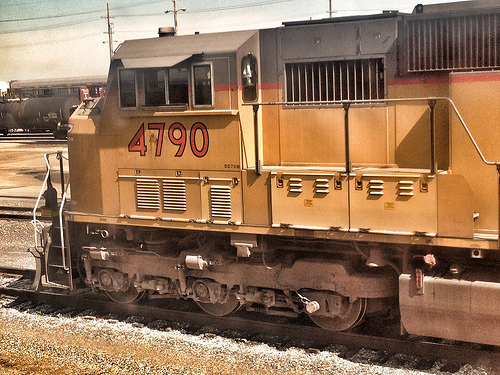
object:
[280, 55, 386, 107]
window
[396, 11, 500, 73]
window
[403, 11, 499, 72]
railing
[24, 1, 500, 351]
train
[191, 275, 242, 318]
wheel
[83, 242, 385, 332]
wheels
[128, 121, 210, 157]
number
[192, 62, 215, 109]
window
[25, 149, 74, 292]
stairs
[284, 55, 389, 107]
railing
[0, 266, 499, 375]
tracks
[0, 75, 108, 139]
coal car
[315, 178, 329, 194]
ventilation slot